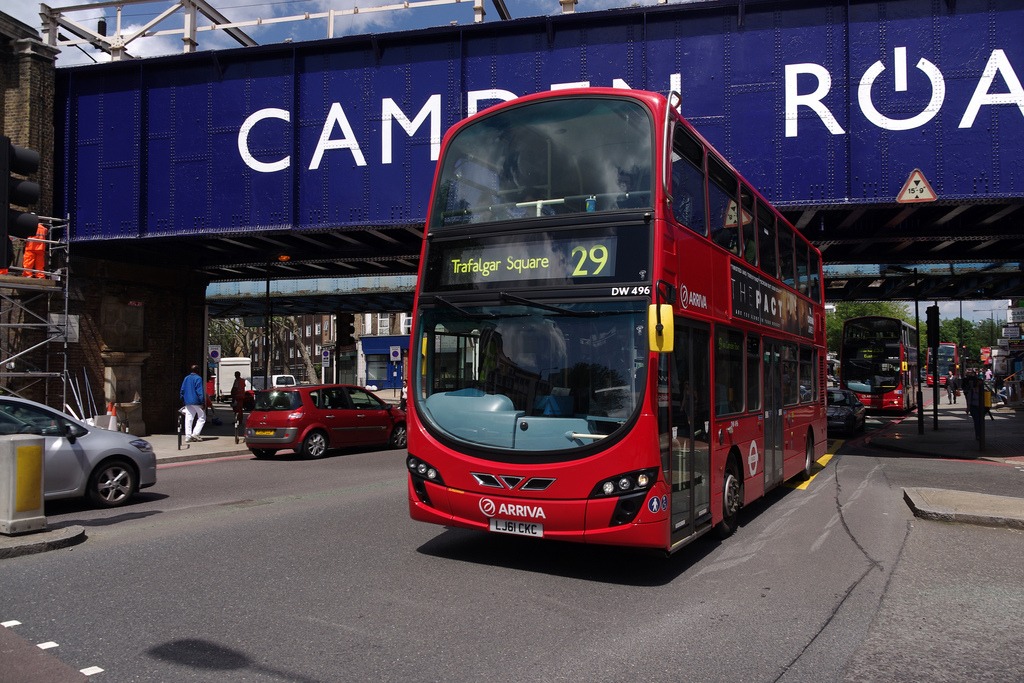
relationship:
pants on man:
[184, 402, 211, 440] [179, 354, 211, 440]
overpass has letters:
[55, 24, 1023, 253] [244, 28, 1023, 174]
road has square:
[8, 381, 1023, 680] [74, 654, 110, 680]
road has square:
[8, 381, 1023, 680] [34, 632, 66, 652]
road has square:
[8, 381, 1023, 680] [4, 607, 24, 637]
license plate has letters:
[488, 517, 545, 538] [488, 517, 545, 538]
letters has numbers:
[488, 517, 545, 538] [488, 517, 545, 538]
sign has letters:
[428, 230, 618, 281] [443, 249, 552, 281]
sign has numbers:
[428, 230, 618, 281] [567, 243, 618, 281]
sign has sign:
[892, 163, 941, 206] [896, 168, 937, 204]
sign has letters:
[892, 163, 941, 206] [892, 163, 941, 206]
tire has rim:
[89, 454, 137, 500] [96, 464, 136, 500]